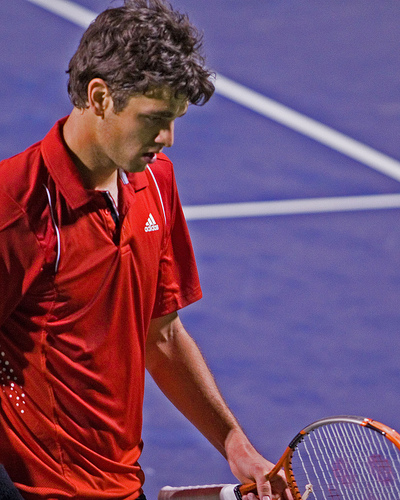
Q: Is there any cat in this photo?
A: No, there are no cats.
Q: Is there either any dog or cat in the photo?
A: No, there are no cats or dogs.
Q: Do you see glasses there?
A: No, there are no glasses.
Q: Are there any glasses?
A: No, there are no glasses.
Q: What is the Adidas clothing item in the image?
A: The clothing item is a shirt.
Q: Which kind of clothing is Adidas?
A: The clothing is a shirt.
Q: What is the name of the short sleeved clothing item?
A: The clothing item is a shirt.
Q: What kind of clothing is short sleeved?
A: The clothing is a shirt.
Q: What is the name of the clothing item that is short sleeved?
A: The clothing item is a shirt.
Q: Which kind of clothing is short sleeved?
A: The clothing is a shirt.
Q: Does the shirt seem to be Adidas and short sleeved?
A: Yes, the shirt is Adidas and short sleeved.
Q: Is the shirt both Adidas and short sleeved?
A: Yes, the shirt is Adidas and short sleeved.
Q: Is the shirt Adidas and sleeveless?
A: No, the shirt is Adidas but short sleeved.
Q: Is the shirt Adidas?
A: Yes, the shirt is adidas.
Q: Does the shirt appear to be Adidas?
A: Yes, the shirt is adidas.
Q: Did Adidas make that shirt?
A: Yes, the shirt was made by adidas.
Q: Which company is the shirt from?
A: The shirt is from adidas.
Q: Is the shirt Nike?
A: No, the shirt is adidas.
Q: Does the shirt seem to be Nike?
A: No, the shirt is adidas.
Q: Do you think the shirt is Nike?
A: No, the shirt is adidas.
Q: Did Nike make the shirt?
A: No, the shirt was made by adidas.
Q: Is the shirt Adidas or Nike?
A: The shirt is adidas.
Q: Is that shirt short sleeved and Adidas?
A: Yes, the shirt is short sleeved and adidas.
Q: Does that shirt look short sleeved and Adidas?
A: Yes, the shirt is short sleeved and adidas.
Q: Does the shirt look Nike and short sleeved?
A: No, the shirt is short sleeved but adidas.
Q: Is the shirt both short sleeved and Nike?
A: No, the shirt is short sleeved but adidas.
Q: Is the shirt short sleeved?
A: Yes, the shirt is short sleeved.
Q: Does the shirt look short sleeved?
A: Yes, the shirt is short sleeved.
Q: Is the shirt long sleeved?
A: No, the shirt is short sleeved.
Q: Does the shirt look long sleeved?
A: No, the shirt is short sleeved.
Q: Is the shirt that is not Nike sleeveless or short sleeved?
A: The shirt is short sleeved.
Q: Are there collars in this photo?
A: Yes, there is a collar.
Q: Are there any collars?
A: Yes, there is a collar.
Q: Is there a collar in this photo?
A: Yes, there is a collar.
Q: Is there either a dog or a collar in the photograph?
A: Yes, there is a collar.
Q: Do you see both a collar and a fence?
A: No, there is a collar but no fences.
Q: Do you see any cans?
A: No, there are no cans.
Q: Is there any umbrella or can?
A: No, there are no cans or umbrellas.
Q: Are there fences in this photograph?
A: No, there are no fences.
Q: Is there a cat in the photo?
A: No, there are no cats.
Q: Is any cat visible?
A: No, there are no cats.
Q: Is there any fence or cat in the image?
A: No, there are no cats or fences.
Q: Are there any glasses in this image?
A: No, there are no glasses.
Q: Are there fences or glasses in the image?
A: No, there are no glasses or fences.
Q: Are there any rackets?
A: Yes, there is a racket.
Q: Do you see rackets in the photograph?
A: Yes, there is a racket.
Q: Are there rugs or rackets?
A: Yes, there is a racket.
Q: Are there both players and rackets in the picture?
A: Yes, there are both a racket and a player.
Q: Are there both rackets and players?
A: Yes, there are both a racket and a player.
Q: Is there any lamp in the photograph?
A: No, there are no lamps.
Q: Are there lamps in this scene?
A: No, there are no lamps.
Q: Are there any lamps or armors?
A: No, there are no lamps or armors.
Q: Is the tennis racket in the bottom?
A: Yes, the tennis racket is in the bottom of the image.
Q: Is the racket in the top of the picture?
A: No, the racket is in the bottom of the image.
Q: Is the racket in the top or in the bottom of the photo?
A: The racket is in the bottom of the image.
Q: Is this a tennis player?
A: Yes, this is a tennis player.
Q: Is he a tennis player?
A: Yes, this is a tennis player.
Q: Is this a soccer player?
A: No, this is a tennis player.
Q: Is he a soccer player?
A: No, this is a tennis player.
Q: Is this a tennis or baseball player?
A: This is a tennis player.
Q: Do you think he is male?
A: Yes, the player is male.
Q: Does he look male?
A: Yes, the player is male.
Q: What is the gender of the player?
A: The player is male.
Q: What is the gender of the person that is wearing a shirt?
A: The player is male.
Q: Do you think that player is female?
A: No, the player is male.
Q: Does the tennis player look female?
A: No, the player is male.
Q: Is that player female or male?
A: The player is male.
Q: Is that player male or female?
A: The player is male.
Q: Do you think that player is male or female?
A: The player is male.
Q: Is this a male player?
A: Yes, this is a male player.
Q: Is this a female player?
A: No, this is a male player.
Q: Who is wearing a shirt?
A: The player is wearing a shirt.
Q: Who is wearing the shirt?
A: The player is wearing a shirt.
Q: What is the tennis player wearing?
A: The player is wearing a shirt.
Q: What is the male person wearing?
A: The player is wearing a shirt.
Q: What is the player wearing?
A: The player is wearing a shirt.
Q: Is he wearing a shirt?
A: Yes, the player is wearing a shirt.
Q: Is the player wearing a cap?
A: No, the player is wearing a shirt.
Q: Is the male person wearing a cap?
A: No, the player is wearing a shirt.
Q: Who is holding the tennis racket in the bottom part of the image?
A: The player is holding the racket.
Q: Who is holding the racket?
A: The player is holding the racket.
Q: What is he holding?
A: The player is holding the racket.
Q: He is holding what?
A: The player is holding the racket.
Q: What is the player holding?
A: The player is holding the racket.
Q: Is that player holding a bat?
A: No, the player is holding the racket.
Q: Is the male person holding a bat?
A: No, the player is holding the racket.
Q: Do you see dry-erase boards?
A: No, there are no dry-erase boards.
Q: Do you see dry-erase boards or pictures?
A: No, there are no dry-erase boards or pictures.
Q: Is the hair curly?
A: Yes, the hair is curly.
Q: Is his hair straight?
A: No, the hair is curly.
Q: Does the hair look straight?
A: No, the hair is curly.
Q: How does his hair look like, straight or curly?
A: The hair is curly.